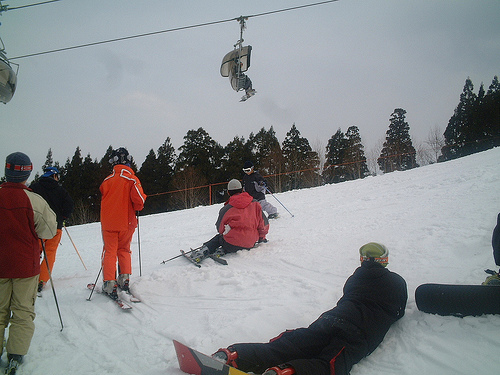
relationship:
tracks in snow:
[49, 288, 214, 375] [10, 141, 499, 374]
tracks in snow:
[396, 160, 499, 232] [10, 141, 499, 374]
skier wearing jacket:
[92, 146, 144, 297] [97, 163, 148, 233]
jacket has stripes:
[97, 163, 148, 233] [100, 162, 147, 204]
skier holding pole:
[92, 146, 144, 297] [136, 208, 144, 276]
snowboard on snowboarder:
[171, 339, 249, 374] [210, 239, 408, 374]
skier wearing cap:
[1, 147, 63, 374] [4, 150, 35, 183]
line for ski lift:
[0, 0, 343, 63] [217, 15, 260, 105]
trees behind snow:
[1, 73, 499, 230] [10, 141, 499, 374]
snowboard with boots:
[171, 339, 249, 374] [214, 341, 296, 374]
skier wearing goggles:
[236, 160, 282, 225] [238, 167, 255, 175]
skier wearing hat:
[236, 160, 282, 225] [237, 160, 254, 170]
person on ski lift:
[230, 61, 258, 104] [217, 15, 260, 105]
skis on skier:
[84, 275, 146, 314] [92, 146, 144, 297]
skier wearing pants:
[92, 146, 144, 297] [98, 227, 139, 284]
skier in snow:
[180, 176, 279, 268] [10, 141, 499, 374]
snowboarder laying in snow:
[210, 239, 408, 374] [10, 141, 499, 374]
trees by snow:
[1, 73, 499, 230] [10, 141, 499, 374]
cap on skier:
[4, 150, 35, 183] [1, 147, 63, 374]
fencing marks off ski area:
[2, 141, 420, 231] [14, 146, 499, 374]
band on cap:
[4, 162, 34, 172] [4, 150, 35, 183]